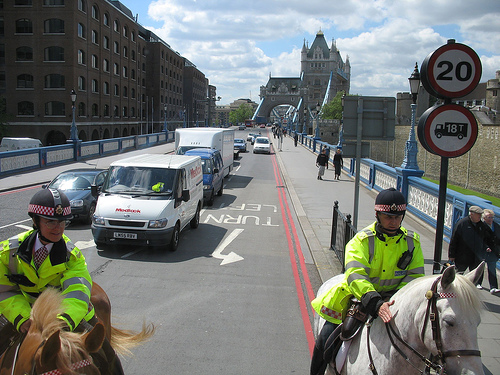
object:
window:
[48, 171, 104, 190]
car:
[45, 167, 109, 224]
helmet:
[374, 187, 408, 216]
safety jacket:
[310, 221, 425, 325]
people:
[316, 149, 330, 181]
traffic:
[44, 119, 273, 251]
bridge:
[0, 123, 500, 374]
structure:
[251, 26, 351, 134]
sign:
[419, 39, 482, 100]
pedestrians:
[332, 148, 343, 179]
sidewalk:
[268, 126, 499, 374]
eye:
[441, 316, 455, 329]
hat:
[469, 206, 484, 214]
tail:
[110, 313, 161, 363]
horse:
[1, 282, 157, 375]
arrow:
[212, 228, 244, 265]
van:
[90, 154, 203, 251]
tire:
[190, 206, 199, 231]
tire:
[170, 224, 179, 250]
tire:
[218, 179, 224, 196]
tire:
[207, 190, 215, 206]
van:
[174, 127, 236, 177]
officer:
[0, 188, 113, 375]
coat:
[0, 229, 96, 334]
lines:
[266, 127, 315, 359]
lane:
[0, 126, 325, 371]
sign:
[417, 103, 478, 158]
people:
[448, 205, 492, 285]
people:
[475, 208, 499, 294]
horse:
[314, 261, 490, 375]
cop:
[310, 187, 426, 374]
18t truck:
[434, 121, 468, 140]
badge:
[391, 204, 397, 211]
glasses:
[34, 217, 70, 229]